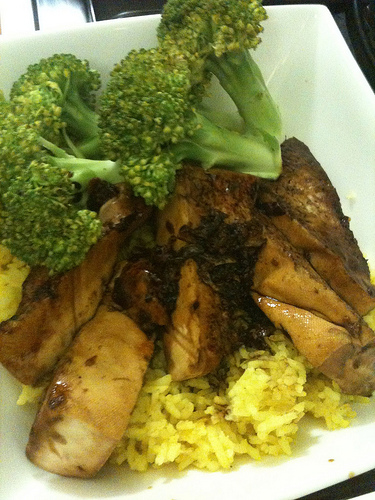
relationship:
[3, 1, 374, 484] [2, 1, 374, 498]
food on top of plate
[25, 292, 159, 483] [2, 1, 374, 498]
chicken on top of plate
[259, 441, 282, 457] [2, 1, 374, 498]
rice on top of plate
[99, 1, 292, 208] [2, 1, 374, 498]
broccoli on top of plate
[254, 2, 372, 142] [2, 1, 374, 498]
corner of plate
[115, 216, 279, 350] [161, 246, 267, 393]
sauce on top of chicken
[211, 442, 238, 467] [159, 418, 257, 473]
part of some rice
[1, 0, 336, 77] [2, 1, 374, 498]
edge of a plate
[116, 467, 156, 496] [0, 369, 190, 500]
part of a shade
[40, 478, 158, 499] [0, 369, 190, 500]
edge of a shade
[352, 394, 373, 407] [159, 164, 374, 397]
rice placed under meat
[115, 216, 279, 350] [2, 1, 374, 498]
sauce on top of plate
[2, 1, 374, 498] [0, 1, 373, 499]
plate sitting on top of sink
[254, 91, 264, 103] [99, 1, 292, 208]
spot on top of broccoli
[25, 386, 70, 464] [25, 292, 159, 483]
dark area of chicken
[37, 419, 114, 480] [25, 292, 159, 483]
light area of chicken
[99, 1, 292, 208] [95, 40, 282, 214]
broccoli with stalk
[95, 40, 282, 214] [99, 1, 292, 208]
stalk of broccoli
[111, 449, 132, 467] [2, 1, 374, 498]
rice on top of plate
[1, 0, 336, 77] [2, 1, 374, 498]
edge of plate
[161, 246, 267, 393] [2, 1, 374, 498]
chicken on top of a plate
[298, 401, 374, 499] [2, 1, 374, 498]
part of a plate